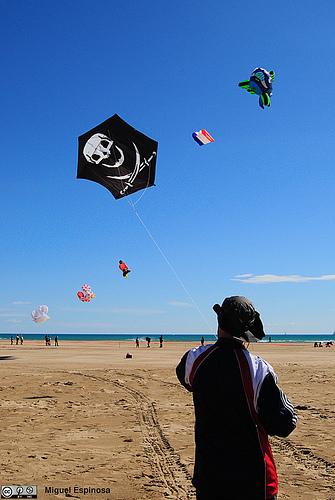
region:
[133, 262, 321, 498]
this is a person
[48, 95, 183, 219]
this is a kite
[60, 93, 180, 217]
the kite is black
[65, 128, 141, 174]
skull on the kite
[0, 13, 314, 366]
multiple kites in sky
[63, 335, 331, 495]
tire tracks on beach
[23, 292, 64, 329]
white kite in sky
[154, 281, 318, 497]
this is a person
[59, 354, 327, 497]
tire tracks in sand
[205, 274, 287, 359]
person wearing a hat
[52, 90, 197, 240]
this is a kite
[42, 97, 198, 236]
the kite is black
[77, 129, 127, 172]
white skull on kite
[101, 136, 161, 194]
white swords on kite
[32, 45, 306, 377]
multiple kites in sky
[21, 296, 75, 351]
this is a white kite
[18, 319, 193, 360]
people standing on the beach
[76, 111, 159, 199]
black and white pirate kite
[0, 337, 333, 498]
brown sandy beach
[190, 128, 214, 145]
blue white and red kite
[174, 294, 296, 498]
person wearing a hat flying a kite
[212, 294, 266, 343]
brownish colored sun hat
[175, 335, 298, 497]
dark blue jacket with red and white accents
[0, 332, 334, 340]
turquoise blue ocean water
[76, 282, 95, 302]
red and white patterned kite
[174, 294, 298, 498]
man flying a pirate kite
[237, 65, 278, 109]
blue green and white kite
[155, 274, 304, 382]
The person has a hat on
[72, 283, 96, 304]
Kite in the sky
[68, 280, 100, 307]
Polka-dotted kite in the sky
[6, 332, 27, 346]
Group of people in the distance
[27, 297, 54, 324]
White kite in the sky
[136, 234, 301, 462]
The person is flying a kite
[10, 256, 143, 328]
Three kites in the air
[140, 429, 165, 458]
a view of marks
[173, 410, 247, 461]
a view of jacket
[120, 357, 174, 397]
a view of sand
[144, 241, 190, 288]
a view of thread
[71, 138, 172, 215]
a view of kite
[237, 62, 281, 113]
a kite in the sky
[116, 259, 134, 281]
a kite in the sky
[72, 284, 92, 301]
a kite in the sky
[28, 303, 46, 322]
a kite in the sky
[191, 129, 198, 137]
a kite in the sky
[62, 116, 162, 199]
a kite in the sky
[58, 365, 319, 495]
tire tracks on the beach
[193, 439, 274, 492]
a red pair of pants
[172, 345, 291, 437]
a black and white jacket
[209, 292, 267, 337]
a brown beach hat